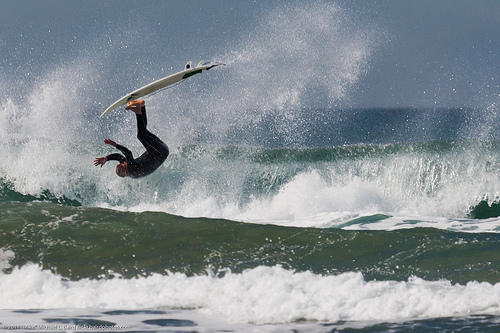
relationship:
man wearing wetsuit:
[97, 101, 171, 178] [105, 116, 167, 176]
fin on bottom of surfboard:
[180, 58, 194, 72] [99, 61, 227, 119]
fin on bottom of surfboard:
[195, 58, 203, 67] [99, 61, 227, 119]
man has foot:
[97, 101, 171, 178] [125, 105, 144, 116]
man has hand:
[97, 101, 171, 178] [95, 156, 106, 170]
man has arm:
[97, 101, 171, 178] [100, 154, 121, 163]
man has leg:
[97, 101, 171, 178] [133, 110, 163, 150]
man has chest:
[97, 101, 171, 178] [130, 155, 142, 164]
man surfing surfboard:
[97, 101, 171, 178] [99, 61, 227, 119]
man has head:
[97, 101, 171, 178] [115, 161, 125, 179]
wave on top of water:
[2, 130, 498, 225] [12, 109, 499, 333]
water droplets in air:
[275, 14, 375, 83] [131, 3, 402, 109]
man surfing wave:
[97, 101, 171, 178] [2, 130, 498, 225]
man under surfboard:
[97, 101, 171, 178] [99, 61, 227, 119]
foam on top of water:
[283, 182, 496, 235] [12, 109, 499, 333]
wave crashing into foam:
[2, 130, 498, 225] [283, 182, 496, 235]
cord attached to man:
[142, 77, 189, 95] [97, 101, 171, 178]